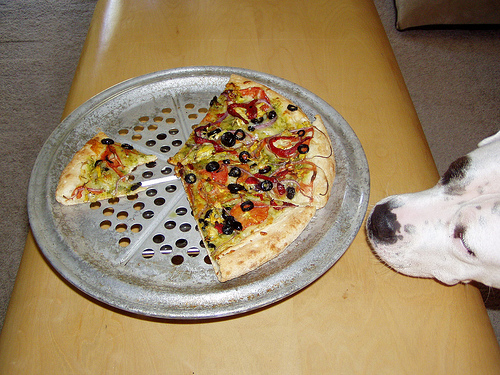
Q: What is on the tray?
A: Pizza.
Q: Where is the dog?
A: On right.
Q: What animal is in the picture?
A: Dog.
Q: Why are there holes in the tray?
A: Steam.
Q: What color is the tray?
A: Silver.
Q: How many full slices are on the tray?
A: Three.